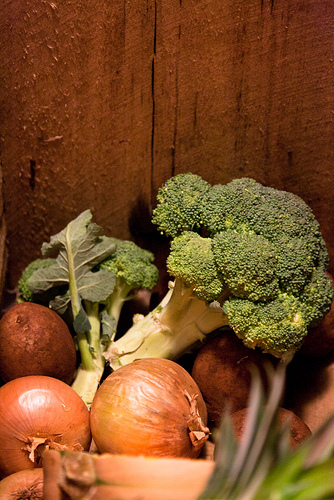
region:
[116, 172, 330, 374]
a piece of broccoli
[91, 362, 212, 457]
a large round onion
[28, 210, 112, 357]
the leaf from a stalk of broccoli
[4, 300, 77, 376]
a potato in a pile of vegetables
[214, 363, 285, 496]
a green leafy vegetable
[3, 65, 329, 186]
the side of a box holding vegetables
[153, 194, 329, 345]
the head of a broccoli stalk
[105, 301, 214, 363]
the stem of a broccoli stalk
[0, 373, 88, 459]
an onion with shiny skin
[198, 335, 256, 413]
a potato under a stalk of broccoli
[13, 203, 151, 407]
piece of green broccoli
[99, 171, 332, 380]
piece of green broccoli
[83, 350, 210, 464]
an onion with brown skin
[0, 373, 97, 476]
an onion with brown skin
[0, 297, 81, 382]
a potato with brown skin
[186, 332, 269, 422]
an potato with brown skin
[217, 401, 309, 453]
an potato with brown skin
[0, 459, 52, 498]
an onion with brown skin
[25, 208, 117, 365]
a green broccoli leaf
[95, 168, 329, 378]
large head of broccoli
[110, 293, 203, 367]
Stalk on a broccoli plant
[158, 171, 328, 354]
Green head of broccoli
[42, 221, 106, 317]
Leaf on a broccoli plant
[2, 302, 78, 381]
Potato in a bunch of vegetables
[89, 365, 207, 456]
Onion in front of broccoli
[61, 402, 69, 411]
Water drop on onion skin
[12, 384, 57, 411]
Light reflection off onion skin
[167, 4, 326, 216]
Wooden plant behind vegetables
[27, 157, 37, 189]
Brown oval in a wooden plank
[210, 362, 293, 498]
Green stems of a vegetable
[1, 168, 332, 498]
Vegetables stacked on top of each other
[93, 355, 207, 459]
Onion is brown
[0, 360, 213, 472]
Two onions next to each other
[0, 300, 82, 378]
Potato is brown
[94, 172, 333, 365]
Large green broccoli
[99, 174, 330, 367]
Bushy broccoli is green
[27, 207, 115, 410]
Leafy green next to onion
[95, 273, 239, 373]
Broccoli stalk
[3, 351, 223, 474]
Two brown onions side by side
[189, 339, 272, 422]
Brown potato under broccoli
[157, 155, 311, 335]
large piece of broccoli floret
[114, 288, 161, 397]
thick stem of broccoli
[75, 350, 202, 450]
small crinkly orange onion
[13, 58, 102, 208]
rough patch of crate wall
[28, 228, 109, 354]
leaf on broccoli stalk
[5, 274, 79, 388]
small brown potato by broccoli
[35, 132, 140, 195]
brown wall of crate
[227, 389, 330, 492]
green leaves of scallion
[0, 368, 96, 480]
small orange with drop of water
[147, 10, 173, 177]
crack in line of brown crate